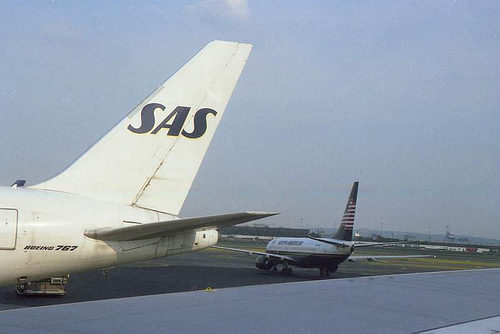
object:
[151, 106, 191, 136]
letter a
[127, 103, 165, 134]
letter s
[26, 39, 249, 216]
tail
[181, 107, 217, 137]
letter s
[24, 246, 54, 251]
word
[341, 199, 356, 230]
flag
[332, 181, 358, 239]
tail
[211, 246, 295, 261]
left wing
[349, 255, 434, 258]
right wing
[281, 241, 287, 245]
letters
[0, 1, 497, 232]
sky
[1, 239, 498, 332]
ground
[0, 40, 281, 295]
airplane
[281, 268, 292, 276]
wheels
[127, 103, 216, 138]
writing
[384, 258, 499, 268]
grass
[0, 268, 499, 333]
sidewalk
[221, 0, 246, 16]
cloud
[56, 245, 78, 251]
767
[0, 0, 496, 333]
airport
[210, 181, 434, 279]
airplane